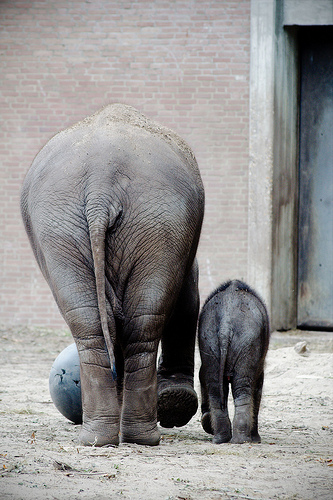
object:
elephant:
[198, 278, 270, 446]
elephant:
[19, 104, 205, 446]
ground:
[0, 326, 333, 500]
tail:
[217, 320, 234, 412]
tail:
[81, 191, 122, 375]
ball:
[47, 343, 85, 425]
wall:
[0, 0, 274, 355]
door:
[274, 26, 333, 334]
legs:
[203, 361, 257, 446]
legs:
[45, 228, 176, 418]